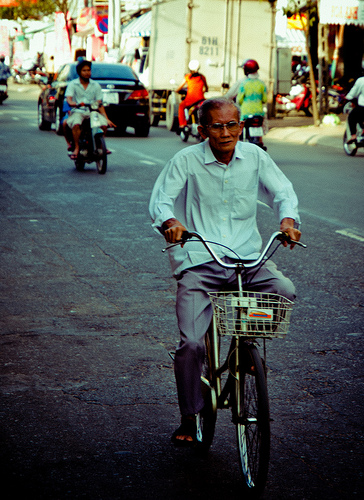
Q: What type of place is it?
A: It is a road.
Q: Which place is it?
A: It is a road.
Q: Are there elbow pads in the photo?
A: No, there are no elbow pads.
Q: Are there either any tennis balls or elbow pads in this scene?
A: No, there are no elbow pads or tennis balls.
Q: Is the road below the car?
A: Yes, the road is below the car.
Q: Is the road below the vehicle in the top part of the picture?
A: Yes, the road is below the car.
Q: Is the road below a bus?
A: No, the road is below the car.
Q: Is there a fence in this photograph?
A: No, there are no fences.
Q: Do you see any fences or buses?
A: No, there are no fences or buses.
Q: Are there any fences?
A: No, there are no fences.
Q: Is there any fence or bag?
A: No, there are no fences or bags.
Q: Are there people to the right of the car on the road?
A: Yes, there is a person to the right of the car.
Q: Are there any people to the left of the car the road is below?
A: No, the person is to the right of the car.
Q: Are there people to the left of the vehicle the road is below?
A: No, the person is to the right of the car.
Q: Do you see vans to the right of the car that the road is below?
A: No, there is a person to the right of the car.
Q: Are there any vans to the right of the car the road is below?
A: No, there is a person to the right of the car.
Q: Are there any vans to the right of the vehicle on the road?
A: No, there is a person to the right of the car.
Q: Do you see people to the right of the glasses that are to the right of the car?
A: Yes, there is a person to the right of the glasses.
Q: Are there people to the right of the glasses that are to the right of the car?
A: Yes, there is a person to the right of the glasses.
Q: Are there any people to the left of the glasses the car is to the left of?
A: No, the person is to the right of the glasses.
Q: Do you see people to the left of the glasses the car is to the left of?
A: No, the person is to the right of the glasses.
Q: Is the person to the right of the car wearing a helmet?
A: Yes, the person is wearing a helmet.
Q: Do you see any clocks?
A: No, there are no clocks.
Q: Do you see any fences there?
A: No, there are no fences.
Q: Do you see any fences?
A: No, there are no fences.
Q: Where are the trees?
A: The trees are on the road.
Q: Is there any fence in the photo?
A: No, there are no fences.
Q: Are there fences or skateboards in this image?
A: No, there are no fences or skateboards.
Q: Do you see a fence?
A: No, there are no fences.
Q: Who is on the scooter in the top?
A: The man is on the scooter.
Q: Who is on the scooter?
A: The man is on the scooter.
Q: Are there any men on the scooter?
A: Yes, there is a man on the scooter.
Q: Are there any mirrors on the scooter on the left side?
A: No, there is a man on the scooter.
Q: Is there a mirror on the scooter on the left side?
A: No, there is a man on the scooter.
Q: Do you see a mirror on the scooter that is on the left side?
A: No, there is a man on the scooter.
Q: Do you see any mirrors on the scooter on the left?
A: No, there is a man on the scooter.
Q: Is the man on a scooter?
A: Yes, the man is on a scooter.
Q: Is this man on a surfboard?
A: No, the man is on a scooter.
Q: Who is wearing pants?
A: The man is wearing pants.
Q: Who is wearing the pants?
A: The man is wearing pants.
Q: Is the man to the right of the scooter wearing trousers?
A: Yes, the man is wearing trousers.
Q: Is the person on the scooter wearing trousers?
A: Yes, the man is wearing trousers.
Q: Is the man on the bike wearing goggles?
A: No, the man is wearing trousers.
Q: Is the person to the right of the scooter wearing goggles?
A: No, the man is wearing trousers.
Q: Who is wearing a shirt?
A: The man is wearing a shirt.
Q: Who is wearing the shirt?
A: The man is wearing a shirt.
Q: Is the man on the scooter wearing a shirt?
A: Yes, the man is wearing a shirt.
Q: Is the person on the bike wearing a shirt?
A: Yes, the man is wearing a shirt.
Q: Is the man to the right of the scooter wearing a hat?
A: No, the man is wearing a shirt.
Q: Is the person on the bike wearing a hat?
A: No, the man is wearing a shirt.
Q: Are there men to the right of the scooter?
A: Yes, there is a man to the right of the scooter.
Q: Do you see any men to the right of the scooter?
A: Yes, there is a man to the right of the scooter.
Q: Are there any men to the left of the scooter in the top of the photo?
A: No, the man is to the right of the scooter.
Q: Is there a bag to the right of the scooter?
A: No, there is a man to the right of the scooter.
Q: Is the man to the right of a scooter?
A: Yes, the man is to the right of a scooter.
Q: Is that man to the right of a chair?
A: No, the man is to the right of a scooter.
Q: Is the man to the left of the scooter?
A: No, the man is to the right of the scooter.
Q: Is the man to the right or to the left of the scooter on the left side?
A: The man is to the right of the scooter.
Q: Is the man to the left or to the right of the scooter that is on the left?
A: The man is to the right of the scooter.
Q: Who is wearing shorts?
A: The man is wearing shorts.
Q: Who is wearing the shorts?
A: The man is wearing shorts.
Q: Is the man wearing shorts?
A: Yes, the man is wearing shorts.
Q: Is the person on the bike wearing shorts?
A: Yes, the man is wearing shorts.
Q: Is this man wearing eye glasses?
A: No, the man is wearing shorts.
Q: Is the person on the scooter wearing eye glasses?
A: No, the man is wearing shorts.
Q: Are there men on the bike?
A: Yes, there is a man on the bike.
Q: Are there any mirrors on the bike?
A: No, there is a man on the bike.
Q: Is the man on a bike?
A: Yes, the man is on a bike.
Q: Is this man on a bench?
A: No, the man is on a bike.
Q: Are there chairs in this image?
A: No, there are no chairs.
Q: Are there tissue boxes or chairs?
A: No, there are no chairs or tissue boxes.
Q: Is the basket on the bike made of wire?
A: Yes, the basket is made of wire.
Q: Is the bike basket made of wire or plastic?
A: The basket is made of wire.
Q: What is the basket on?
A: The basket is on the bike.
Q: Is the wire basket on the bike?
A: Yes, the basket is on the bike.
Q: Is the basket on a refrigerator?
A: No, the basket is on the bike.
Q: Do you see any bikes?
A: Yes, there is a bike.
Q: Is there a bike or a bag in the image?
A: Yes, there is a bike.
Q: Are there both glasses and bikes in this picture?
A: Yes, there are both a bike and glasses.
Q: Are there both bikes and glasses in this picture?
A: Yes, there are both a bike and glasses.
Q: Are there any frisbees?
A: No, there are no frisbees.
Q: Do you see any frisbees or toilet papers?
A: No, there are no frisbees or toilet papers.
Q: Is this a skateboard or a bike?
A: This is a bike.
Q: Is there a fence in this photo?
A: No, there are no fences.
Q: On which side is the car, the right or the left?
A: The car is on the left of the image.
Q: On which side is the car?
A: The car is on the left of the image.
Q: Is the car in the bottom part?
A: No, the car is in the top of the image.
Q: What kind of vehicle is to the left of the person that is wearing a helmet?
A: The vehicle is a car.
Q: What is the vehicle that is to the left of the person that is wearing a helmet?
A: The vehicle is a car.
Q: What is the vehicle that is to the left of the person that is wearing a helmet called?
A: The vehicle is a car.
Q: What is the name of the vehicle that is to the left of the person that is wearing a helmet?
A: The vehicle is a car.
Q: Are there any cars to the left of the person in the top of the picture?
A: Yes, there is a car to the left of the person.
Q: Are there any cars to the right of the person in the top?
A: No, the car is to the left of the person.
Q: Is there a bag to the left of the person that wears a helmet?
A: No, there is a car to the left of the person.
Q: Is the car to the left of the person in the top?
A: Yes, the car is to the left of the person.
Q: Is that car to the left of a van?
A: No, the car is to the left of the person.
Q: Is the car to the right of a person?
A: No, the car is to the left of a person.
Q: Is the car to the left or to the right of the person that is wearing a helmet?
A: The car is to the left of the person.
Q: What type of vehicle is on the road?
A: The vehicle is a car.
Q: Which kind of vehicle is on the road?
A: The vehicle is a car.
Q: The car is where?
A: The car is on the road.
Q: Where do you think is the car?
A: The car is on the road.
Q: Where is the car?
A: The car is on the road.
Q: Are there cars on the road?
A: Yes, there is a car on the road.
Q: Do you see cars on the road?
A: Yes, there is a car on the road.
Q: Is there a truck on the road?
A: No, there is a car on the road.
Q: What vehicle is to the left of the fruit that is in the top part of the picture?
A: The vehicle is a car.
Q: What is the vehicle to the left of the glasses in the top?
A: The vehicle is a car.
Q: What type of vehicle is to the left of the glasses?
A: The vehicle is a car.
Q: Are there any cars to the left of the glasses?
A: Yes, there is a car to the left of the glasses.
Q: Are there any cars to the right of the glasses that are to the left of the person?
A: No, the car is to the left of the glasses.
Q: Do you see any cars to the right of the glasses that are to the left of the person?
A: No, the car is to the left of the glasses.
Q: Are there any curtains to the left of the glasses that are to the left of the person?
A: No, there is a car to the left of the glasses.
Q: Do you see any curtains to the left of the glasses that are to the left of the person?
A: No, there is a car to the left of the glasses.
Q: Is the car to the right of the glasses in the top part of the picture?
A: No, the car is to the left of the glasses.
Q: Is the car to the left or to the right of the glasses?
A: The car is to the left of the glasses.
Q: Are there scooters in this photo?
A: Yes, there is a scooter.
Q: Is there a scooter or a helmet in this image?
A: Yes, there is a scooter.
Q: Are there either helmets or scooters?
A: Yes, there is a scooter.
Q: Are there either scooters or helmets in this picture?
A: Yes, there is a scooter.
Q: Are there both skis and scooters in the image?
A: No, there is a scooter but no skis.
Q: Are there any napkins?
A: No, there are no napkins.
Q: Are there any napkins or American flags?
A: No, there are no napkins or American flags.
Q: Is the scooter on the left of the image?
A: Yes, the scooter is on the left of the image.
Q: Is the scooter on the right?
A: No, the scooter is on the left of the image.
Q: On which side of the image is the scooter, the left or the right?
A: The scooter is on the left of the image.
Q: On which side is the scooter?
A: The scooter is on the left of the image.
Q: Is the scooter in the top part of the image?
A: Yes, the scooter is in the top of the image.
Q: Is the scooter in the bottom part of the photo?
A: No, the scooter is in the top of the image.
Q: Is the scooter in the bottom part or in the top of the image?
A: The scooter is in the top of the image.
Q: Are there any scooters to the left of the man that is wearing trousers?
A: Yes, there is a scooter to the left of the man.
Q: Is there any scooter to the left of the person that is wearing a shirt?
A: Yes, there is a scooter to the left of the man.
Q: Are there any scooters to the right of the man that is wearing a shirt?
A: No, the scooter is to the left of the man.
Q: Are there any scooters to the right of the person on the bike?
A: No, the scooter is to the left of the man.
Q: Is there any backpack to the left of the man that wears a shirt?
A: No, there is a scooter to the left of the man.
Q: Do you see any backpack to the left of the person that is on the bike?
A: No, there is a scooter to the left of the man.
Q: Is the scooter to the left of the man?
A: Yes, the scooter is to the left of the man.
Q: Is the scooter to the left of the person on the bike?
A: Yes, the scooter is to the left of the man.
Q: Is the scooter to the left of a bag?
A: No, the scooter is to the left of the man.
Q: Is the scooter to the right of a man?
A: No, the scooter is to the left of a man.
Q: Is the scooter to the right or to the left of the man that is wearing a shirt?
A: The scooter is to the left of the man.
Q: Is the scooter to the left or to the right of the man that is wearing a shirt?
A: The scooter is to the left of the man.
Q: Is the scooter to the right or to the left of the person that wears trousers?
A: The scooter is to the left of the man.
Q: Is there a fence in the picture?
A: No, there are no fences.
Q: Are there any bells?
A: No, there are no bells.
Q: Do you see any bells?
A: No, there are no bells.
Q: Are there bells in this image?
A: No, there are no bells.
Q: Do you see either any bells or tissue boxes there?
A: No, there are no bells or tissue boxes.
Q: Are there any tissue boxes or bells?
A: No, there are no bells or tissue boxes.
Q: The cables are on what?
A: The cables are on the bike.